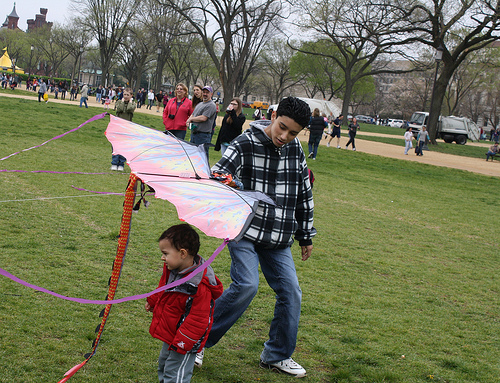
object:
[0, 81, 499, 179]
path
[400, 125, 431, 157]
couple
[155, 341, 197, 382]
grey trouser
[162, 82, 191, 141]
person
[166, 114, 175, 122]
camera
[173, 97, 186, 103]
neck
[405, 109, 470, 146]
truck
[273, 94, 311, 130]
hair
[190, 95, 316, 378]
boys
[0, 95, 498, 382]
grass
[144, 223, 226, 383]
boy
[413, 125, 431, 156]
person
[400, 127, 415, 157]
person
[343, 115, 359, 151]
person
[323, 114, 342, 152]
person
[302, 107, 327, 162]
person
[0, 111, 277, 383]
kite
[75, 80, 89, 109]
people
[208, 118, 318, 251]
hoodie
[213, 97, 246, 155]
lady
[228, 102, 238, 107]
glasses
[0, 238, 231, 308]
tails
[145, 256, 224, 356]
coat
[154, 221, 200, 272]
head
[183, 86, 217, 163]
people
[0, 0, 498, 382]
park